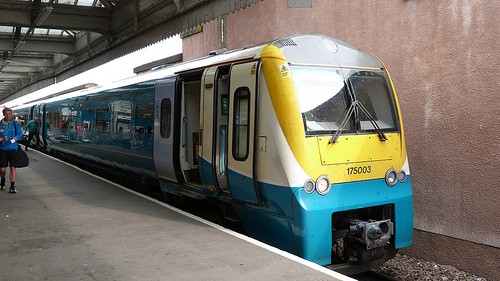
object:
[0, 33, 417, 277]
train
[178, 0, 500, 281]
wall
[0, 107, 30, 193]
passenger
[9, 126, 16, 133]
blue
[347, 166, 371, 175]
number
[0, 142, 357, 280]
platform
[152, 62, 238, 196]
door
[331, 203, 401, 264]
connector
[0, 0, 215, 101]
overhang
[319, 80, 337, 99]
light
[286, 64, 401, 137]
windshield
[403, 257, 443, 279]
gravel